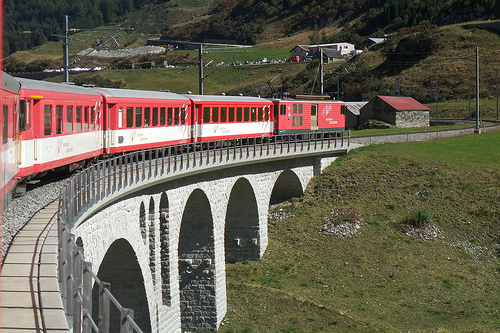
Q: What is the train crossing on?
A: Bridge.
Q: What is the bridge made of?
A: Stone.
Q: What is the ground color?
A: Green.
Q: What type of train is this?
A: Passenger.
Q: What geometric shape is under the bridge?
A: Arch.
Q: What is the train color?
A: Red.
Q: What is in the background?
A: Hills.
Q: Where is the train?
A: On the tracks.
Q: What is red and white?
A: Train.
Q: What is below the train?
A: Tracks.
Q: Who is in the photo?
A: No people.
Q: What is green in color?
A: Grass.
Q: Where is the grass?
A: Next to the train.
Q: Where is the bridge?
A: Under the train.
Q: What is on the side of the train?
A: Windows.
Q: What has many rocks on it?
A: The hill.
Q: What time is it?
A: Afternoon.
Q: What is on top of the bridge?
A: Railroad track.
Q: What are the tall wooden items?
A: Power lines.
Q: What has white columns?
A: Large dome.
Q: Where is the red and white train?
A: On track.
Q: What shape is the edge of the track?
A: Curved.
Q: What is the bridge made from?
A: Stone and metal.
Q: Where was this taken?
A: On a bridge.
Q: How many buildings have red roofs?
A: One.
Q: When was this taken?
A: During the day.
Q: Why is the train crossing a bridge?
A: To get to the other side.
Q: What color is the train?
A: Red and white.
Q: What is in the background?
A: Buildings.